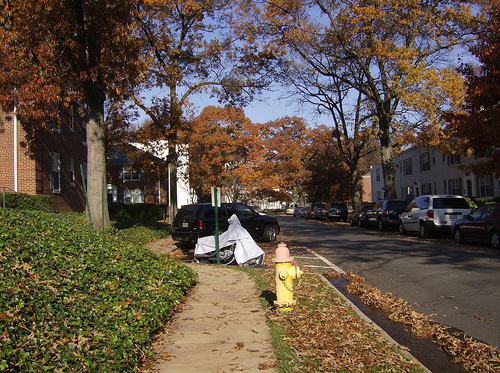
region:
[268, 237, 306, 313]
yellow and red fire hydrant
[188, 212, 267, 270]
motorcycle covered with white cloth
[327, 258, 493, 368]
row of brown leaves along curb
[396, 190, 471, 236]
white minivan parked at curb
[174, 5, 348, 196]
several brown leafed trees with blue sky in background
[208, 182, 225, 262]
back view of sign on green metal post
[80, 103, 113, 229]
broad light brown tree trunk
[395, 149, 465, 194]
two story building in shadow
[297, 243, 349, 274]
broad white lines on street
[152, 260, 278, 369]
light colored sidewalk with leaves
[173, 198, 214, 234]
black suv parked on the side of the street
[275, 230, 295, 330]
fire hydrant near a street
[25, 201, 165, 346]
shrubs near a side walk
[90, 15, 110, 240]
tall tree next to a side walk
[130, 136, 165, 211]
house on a street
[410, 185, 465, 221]
white suv on the side of a street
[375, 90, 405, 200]
tall tree on a street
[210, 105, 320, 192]
trees on a street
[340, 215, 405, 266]
street with cars parked on the side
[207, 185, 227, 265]
traffic sign near a street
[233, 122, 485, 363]
a quiet street in autumn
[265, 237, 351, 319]
fire hydrant near the curb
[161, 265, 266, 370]
a stretch of sidewalk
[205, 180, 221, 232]
the back of a street sign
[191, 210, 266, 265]
covered parked motorcycle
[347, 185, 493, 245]
row of parked cars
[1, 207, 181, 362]
ground cover sloping down to the sidewalk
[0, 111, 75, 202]
edge of a brick building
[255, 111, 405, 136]
the sky through the tops of trees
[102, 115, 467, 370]
a quiet residential street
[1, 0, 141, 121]
The tree's leaves are brown.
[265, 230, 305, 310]
A yellow fire hydrant.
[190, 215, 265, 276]
A parked motorcycle.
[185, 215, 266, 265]
The motorcycle is covered by a tarp.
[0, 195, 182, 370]
A long low bush.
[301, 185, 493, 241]
A column of parked cars.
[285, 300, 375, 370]
Dead leaves.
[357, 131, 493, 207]
A large housing complex.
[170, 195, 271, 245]
A black SUV.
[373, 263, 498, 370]
Dead leaves in a puddle of water.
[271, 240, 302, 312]
a yellow fire hydrant on the street curb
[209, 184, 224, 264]
a street sign on the street curb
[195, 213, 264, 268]
a white motorcycle tarp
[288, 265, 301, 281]
the hose coupler valve on the hydrant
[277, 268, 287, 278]
the discharge valve on the hydrant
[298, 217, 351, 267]
the white street lines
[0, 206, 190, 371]
thick grass on the yard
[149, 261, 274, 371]
a street lined sidewalk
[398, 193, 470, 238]
a white mini van parked at the curb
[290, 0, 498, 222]
large trees lining the street